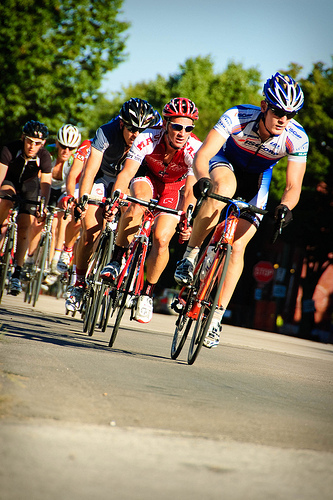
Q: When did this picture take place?
A: It took place in the day time.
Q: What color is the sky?
A: The sky is blue.